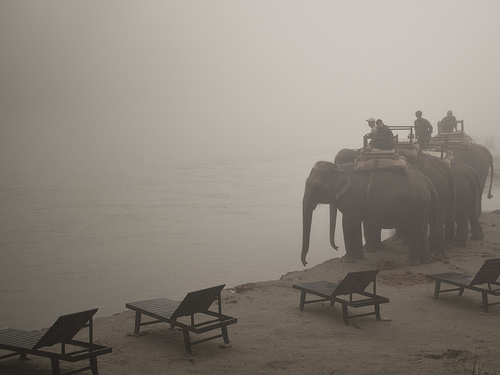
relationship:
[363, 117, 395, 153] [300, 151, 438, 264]
man on elephant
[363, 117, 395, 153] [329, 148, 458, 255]
man on elephant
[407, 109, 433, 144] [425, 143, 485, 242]
man on elephant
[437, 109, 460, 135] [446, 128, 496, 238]
man on elephant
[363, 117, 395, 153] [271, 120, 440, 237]
man on elephant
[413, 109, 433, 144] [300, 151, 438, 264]
man on elephant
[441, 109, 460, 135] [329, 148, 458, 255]
man on elephant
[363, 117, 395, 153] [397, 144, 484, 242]
man on elephant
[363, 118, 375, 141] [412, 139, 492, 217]
man on elephant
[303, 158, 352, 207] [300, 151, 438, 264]
head of elephant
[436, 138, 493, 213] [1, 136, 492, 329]
elephant next to water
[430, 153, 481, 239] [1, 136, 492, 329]
elephant next to water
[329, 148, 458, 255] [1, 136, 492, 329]
elephant next to water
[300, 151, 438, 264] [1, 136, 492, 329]
elephant next to water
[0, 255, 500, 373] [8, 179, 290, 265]
chairs next to water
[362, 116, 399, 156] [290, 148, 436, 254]
person on elephant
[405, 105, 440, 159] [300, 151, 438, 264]
person on elephant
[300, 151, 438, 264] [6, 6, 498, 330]
elephant next to water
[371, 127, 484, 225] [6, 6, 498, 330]
elephant next to water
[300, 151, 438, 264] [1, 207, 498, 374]
elephant on beach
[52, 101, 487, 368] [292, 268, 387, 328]
beach has beach chair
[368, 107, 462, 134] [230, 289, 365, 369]
people at beach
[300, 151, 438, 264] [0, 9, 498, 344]
elephant in fog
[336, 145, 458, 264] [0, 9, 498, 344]
elephant in fog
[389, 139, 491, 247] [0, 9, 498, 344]
elephant in fog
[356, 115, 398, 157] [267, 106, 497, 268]
people on elephants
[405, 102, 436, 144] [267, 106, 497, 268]
people on elephants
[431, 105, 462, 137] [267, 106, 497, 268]
people on elephants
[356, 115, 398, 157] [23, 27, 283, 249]
people in fog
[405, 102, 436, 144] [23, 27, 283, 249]
people in fog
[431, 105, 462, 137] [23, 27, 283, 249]
people in fog